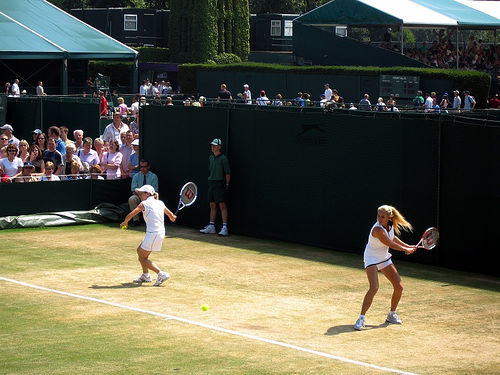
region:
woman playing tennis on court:
[330, 180, 461, 342]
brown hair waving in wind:
[393, 208, 416, 233]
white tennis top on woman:
[359, 229, 399, 276]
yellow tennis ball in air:
[194, 303, 213, 322]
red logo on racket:
[428, 230, 436, 246]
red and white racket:
[425, 223, 445, 247]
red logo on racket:
[184, 187, 198, 197]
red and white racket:
[175, 178, 205, 211]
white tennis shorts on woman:
[136, 230, 166, 256]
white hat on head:
[135, 182, 158, 193]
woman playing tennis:
[346, 186, 440, 342]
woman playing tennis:
[101, 170, 214, 317]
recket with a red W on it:
[172, 171, 202, 224]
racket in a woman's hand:
[406, 217, 451, 264]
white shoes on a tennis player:
[339, 304, 409, 333]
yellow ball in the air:
[191, 290, 217, 318]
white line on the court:
[142, 295, 179, 332]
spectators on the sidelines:
[20, 130, 82, 177]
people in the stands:
[413, 31, 498, 84]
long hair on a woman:
[376, 194, 418, 247]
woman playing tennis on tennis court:
[104, 165, 215, 298]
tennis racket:
[165, 173, 204, 226]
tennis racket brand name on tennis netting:
[182, 181, 197, 203]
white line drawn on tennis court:
[5, 276, 390, 373]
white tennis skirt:
[130, 228, 172, 258]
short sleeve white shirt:
[131, 195, 172, 234]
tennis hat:
[131, 179, 158, 196]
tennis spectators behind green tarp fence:
[2, 108, 142, 180]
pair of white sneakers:
[193, 218, 232, 240]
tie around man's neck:
[140, 173, 148, 187]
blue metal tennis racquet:
[176, 181, 198, 215]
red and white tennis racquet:
[417, 225, 440, 255]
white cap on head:
[134, 184, 156, 196]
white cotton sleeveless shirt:
[141, 194, 166, 232]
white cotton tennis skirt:
[139, 229, 165, 252]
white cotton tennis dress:
[365, 223, 396, 272]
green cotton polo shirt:
[207, 153, 229, 184]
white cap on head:
[211, 137, 222, 146]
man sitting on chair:
[128, 159, 161, 228]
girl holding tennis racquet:
[354, 204, 438, 330]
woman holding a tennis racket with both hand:
[354, 204, 438, 332]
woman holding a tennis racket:
[119, 180, 198, 284]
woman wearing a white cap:
[120, 180, 199, 286]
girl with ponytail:
[351, 200, 420, 332]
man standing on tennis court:
[195, 135, 230, 237]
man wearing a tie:
[128, 160, 160, 224]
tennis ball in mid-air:
[198, 302, 210, 314]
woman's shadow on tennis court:
[88, 279, 158, 290]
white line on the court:
[0, 276, 427, 374]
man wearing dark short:
[198, 135, 234, 235]